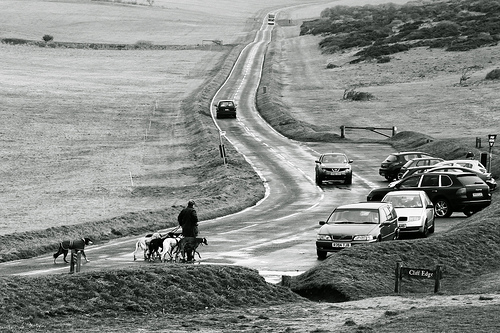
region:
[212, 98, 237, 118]
Car traveling on the road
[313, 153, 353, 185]
A car driving on the road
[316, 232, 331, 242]
Front right headlight on a vehicle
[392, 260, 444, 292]
A sign staked into the grass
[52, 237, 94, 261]
Big dog walking on a road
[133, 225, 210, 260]
Dogs being walked by leashes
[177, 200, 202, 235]
A man wearing a coat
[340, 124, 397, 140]
A gate barricade in an entry way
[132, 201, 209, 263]
A bunch of dogs beign walked by a man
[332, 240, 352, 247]
License plate on a car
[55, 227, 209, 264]
group of dogs on the road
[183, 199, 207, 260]
man standing with dogs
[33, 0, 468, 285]
road the cars and man are traveling on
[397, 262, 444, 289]
sign with white lettering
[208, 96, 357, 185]
car driving on the road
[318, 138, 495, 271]
cars parked next to road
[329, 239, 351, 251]
front license plate of parked car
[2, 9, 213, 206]
pasture on the left sie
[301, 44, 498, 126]
pasture on the right side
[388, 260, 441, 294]
sign next to road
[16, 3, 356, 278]
two laned country road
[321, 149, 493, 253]
cars parked on side of road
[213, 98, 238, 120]
back of car on road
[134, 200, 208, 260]
man with dogs on leashes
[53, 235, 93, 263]
walking dog in vest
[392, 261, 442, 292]
sign on two posts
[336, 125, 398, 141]
gate between two hills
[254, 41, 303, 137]
short hill on side of road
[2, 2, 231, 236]
field of trimmed grass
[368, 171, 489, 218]
parked car facing road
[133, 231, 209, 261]
a group of dogs being walked on the road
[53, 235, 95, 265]
a lone dog on the road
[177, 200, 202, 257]
a man walking dogs on the road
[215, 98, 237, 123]
a car driving on the road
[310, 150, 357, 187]
a car driving on the road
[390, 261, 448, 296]
a sign identifying the site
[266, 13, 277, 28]
a bus driving on the road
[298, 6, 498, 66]
scrub brush in the distance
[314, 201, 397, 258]
a parked car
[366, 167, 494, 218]
a parked car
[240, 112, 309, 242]
A road with tarmac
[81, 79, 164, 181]
Farmlands in the photo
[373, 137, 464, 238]
Cars parked on the roadside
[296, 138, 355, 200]
Car on the road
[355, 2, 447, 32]
Trees in the photo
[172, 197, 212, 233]
A man on the road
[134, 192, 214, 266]
A man with dogs following him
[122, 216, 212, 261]
Dogs on the road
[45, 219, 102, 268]
A dog in the photo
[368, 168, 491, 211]
A car in the photo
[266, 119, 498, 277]
cars on the street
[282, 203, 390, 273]
front of the car